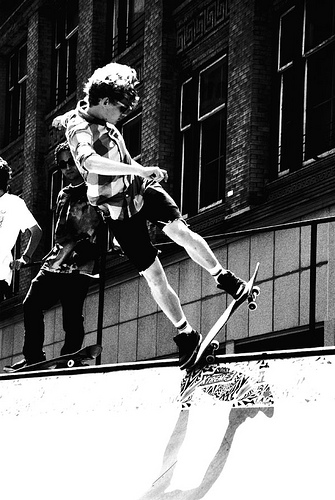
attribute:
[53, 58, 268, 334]
skateboarder — male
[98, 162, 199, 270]
shorts — black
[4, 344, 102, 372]
skateboard — dark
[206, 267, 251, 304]
shoe — black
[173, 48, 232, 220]
windows — rectangular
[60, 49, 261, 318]
men — enjoying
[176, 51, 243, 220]
windows — Big 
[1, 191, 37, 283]
t shirt — white 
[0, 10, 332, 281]
building — brick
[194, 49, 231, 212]
window — big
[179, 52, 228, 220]
window — large, multi-paned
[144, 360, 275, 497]
shadow — black , white 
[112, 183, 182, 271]
shorts — dark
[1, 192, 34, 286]
t-shirt — white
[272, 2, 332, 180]
big windows — Big 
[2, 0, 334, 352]
building —  side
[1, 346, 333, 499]
skate wall — printed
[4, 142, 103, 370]
skateboarder — male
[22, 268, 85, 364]
pants — black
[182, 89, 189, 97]
windows — big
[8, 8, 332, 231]
wall — brick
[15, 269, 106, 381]
pants — black 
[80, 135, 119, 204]
shirt — plaid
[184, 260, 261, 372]
skateboard — for skate, white , black 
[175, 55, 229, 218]
window — big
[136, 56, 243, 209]
windows — glass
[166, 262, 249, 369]
feet — sneakered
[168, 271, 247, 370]
sneakers — dark 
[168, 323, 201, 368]
skating shoe — black 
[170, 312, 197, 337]
sock — white , black 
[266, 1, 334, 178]
window — big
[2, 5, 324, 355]
building. — side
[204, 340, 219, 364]
skateboard — back 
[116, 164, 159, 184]
wrist — man's left